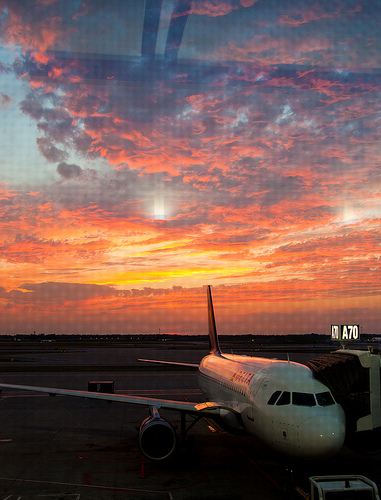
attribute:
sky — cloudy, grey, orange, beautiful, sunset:
[16, 22, 374, 278]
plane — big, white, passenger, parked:
[17, 273, 375, 462]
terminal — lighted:
[300, 299, 373, 392]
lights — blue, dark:
[82, 330, 372, 351]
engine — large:
[129, 420, 169, 467]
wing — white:
[23, 385, 219, 440]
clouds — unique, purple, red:
[48, 65, 356, 198]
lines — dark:
[8, 41, 149, 74]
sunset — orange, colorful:
[27, 165, 372, 281]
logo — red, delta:
[220, 366, 263, 389]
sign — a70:
[325, 309, 369, 353]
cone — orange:
[64, 450, 165, 494]